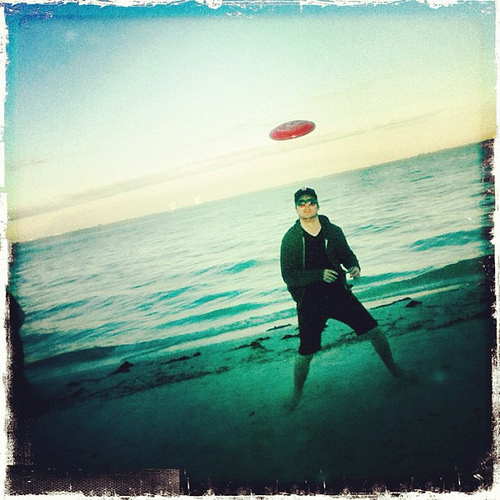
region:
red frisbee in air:
[257, 109, 344, 164]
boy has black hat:
[301, 184, 315, 198]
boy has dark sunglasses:
[294, 197, 326, 209]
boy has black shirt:
[292, 209, 344, 292]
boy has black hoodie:
[282, 227, 353, 292]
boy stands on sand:
[245, 183, 445, 388]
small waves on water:
[57, 195, 435, 380]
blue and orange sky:
[66, 44, 443, 182]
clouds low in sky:
[103, 63, 431, 213]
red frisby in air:
[261, 112, 320, 152]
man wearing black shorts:
[311, 304, 323, 333]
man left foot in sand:
[275, 391, 302, 424]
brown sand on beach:
[330, 383, 368, 428]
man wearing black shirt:
[312, 242, 320, 257]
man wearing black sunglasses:
[297, 198, 317, 207]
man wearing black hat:
[296, 188, 301, 197]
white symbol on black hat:
[299, 186, 309, 193]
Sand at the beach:
[25, 283, 491, 485]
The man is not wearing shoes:
[285, 364, 418, 408]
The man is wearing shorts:
[296, 290, 378, 357]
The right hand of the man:
[322, 268, 340, 282]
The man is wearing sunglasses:
[297, 196, 317, 207]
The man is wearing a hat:
[294, 187, 314, 202]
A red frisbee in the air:
[270, 119, 315, 141]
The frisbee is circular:
[269, 119, 314, 140]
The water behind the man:
[11, 138, 491, 386]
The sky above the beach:
[8, 1, 494, 245]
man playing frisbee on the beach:
[215, 124, 434, 397]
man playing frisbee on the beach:
[167, 115, 411, 464]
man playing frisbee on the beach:
[206, 130, 429, 442]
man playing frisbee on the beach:
[250, 113, 413, 427]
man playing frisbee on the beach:
[219, 120, 413, 428]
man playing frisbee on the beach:
[237, 105, 414, 427]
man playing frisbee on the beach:
[180, 95, 410, 435]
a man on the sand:
[202, 144, 482, 499]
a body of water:
[82, 237, 257, 333]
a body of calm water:
[64, 227, 264, 373]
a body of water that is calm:
[47, 231, 246, 322]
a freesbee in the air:
[247, 116, 328, 144]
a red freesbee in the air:
[273, 120, 321, 150]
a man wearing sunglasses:
[229, 182, 457, 397]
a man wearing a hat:
[284, 163, 424, 410]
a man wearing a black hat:
[260, 156, 428, 465]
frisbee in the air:
[265, 105, 324, 160]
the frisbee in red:
[251, 108, 328, 158]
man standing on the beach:
[268, 180, 410, 415]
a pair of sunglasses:
[288, 193, 324, 213]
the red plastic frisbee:
[267, 117, 316, 141]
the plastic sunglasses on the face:
[295, 198, 319, 207]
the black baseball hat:
[293, 185, 317, 197]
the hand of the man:
[322, 268, 337, 280]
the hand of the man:
[347, 265, 361, 279]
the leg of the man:
[289, 303, 326, 390]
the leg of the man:
[332, 290, 397, 374]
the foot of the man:
[282, 389, 303, 411]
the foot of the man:
[392, 367, 413, 379]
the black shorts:
[295, 289, 375, 353]